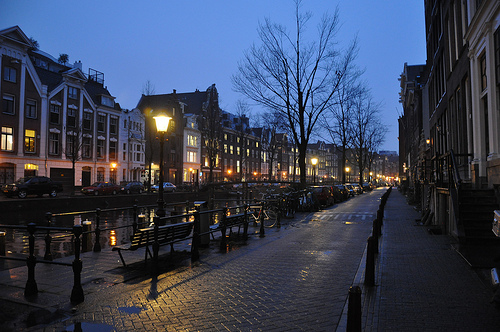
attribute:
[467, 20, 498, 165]
frame — white color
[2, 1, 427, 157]
sky — blue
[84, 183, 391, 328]
road — side